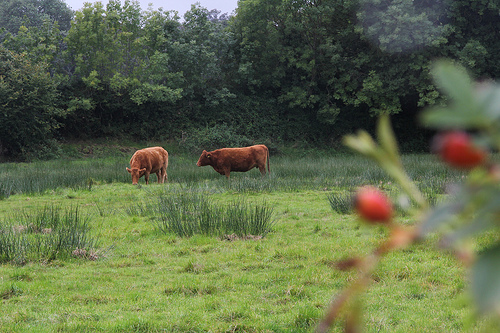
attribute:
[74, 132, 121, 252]
grass — green, tall, taller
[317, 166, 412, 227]
flower — red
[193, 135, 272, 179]
cow — brown, standing, eating, animal, alone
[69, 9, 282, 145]
trees — green, dark, bushy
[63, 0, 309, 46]
sky — blue, grey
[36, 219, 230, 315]
dirt — brown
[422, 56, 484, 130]
leaf — green, blurred